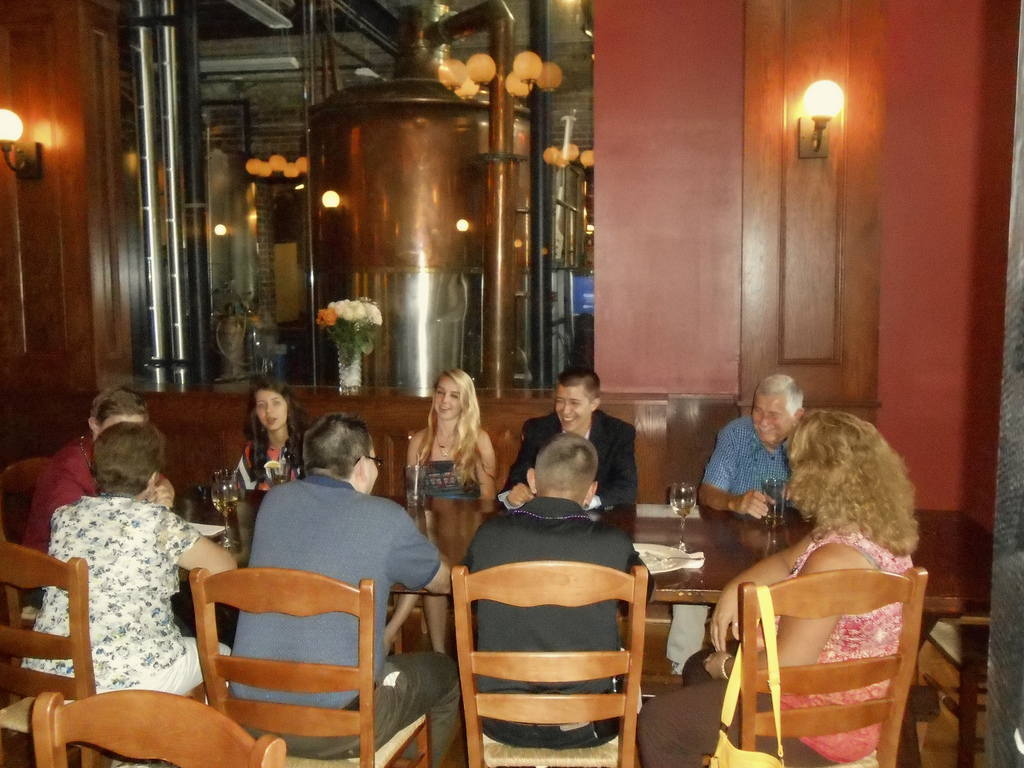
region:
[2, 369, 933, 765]
family sitting around dinner table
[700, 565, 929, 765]
yellow purse hanging off chair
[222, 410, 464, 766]
man wearing blue shirt and gray pants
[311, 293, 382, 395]
white and orange flowers in glass vase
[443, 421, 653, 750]
man wearing shiny black jacket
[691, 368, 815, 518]
older man is laughing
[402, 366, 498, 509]
young woman with long blonde hair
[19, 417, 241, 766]
woman wearing floral shirt and white pants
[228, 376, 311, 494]
young woman with long wavy brown hair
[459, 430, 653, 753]
Man wearing a black sweater.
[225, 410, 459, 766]
Man wearing a blue shirt.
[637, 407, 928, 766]
Woman wearing a red and white top.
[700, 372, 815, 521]
Man wearing a blue shirt.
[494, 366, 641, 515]
Man wearing a black suit jacket.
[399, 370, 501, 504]
Girl with long blond hair.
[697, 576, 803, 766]
Yellow bag hanging on chair.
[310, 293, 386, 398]
White and pink flowers inside a vase.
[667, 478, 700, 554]
Empty wine glass on top of table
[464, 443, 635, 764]
boy at a table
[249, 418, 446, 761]
boy at a table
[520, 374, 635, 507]
boy at a table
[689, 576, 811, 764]
yellow purse hanging on chair.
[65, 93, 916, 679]
the people are gathered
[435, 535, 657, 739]
the chairs are wooden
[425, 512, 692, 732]
the chair is brown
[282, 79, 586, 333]
this is a metal tank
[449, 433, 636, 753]
person sitting at table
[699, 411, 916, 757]
person sitting at table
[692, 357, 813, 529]
person sitting at table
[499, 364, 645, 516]
person sitting at table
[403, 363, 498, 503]
person sitting at table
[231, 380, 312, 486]
person sitting at table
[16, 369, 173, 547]
person sitting at table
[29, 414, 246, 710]
person sitting at table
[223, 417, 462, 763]
person sitting at table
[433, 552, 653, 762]
large wooden dining chair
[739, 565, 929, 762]
wooden dining room chair